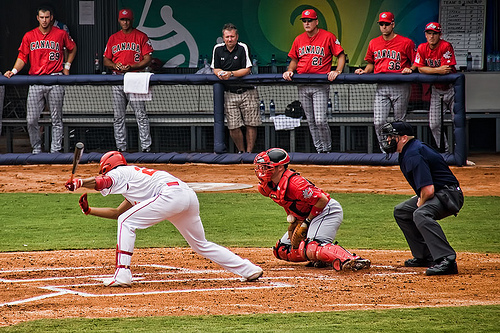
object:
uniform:
[15, 26, 71, 154]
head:
[99, 149, 129, 173]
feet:
[238, 265, 268, 283]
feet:
[101, 277, 131, 286]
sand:
[1, 247, 500, 324]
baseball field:
[1, 157, 500, 332]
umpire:
[376, 121, 466, 276]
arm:
[79, 176, 113, 192]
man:
[65, 149, 262, 286]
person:
[253, 147, 371, 270]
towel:
[123, 71, 156, 103]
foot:
[100, 277, 122, 286]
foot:
[248, 270, 263, 280]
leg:
[113, 198, 165, 273]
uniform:
[285, 28, 345, 152]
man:
[414, 20, 457, 155]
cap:
[298, 7, 319, 18]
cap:
[115, 7, 134, 19]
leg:
[170, 214, 254, 272]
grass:
[0, 191, 500, 256]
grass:
[0, 303, 500, 332]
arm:
[92, 198, 134, 218]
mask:
[250, 150, 275, 188]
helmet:
[95, 149, 130, 175]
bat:
[66, 142, 87, 188]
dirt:
[0, 246, 500, 323]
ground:
[0, 157, 499, 332]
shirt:
[396, 138, 458, 197]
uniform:
[100, 164, 262, 282]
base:
[94, 275, 149, 282]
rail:
[0, 75, 461, 85]